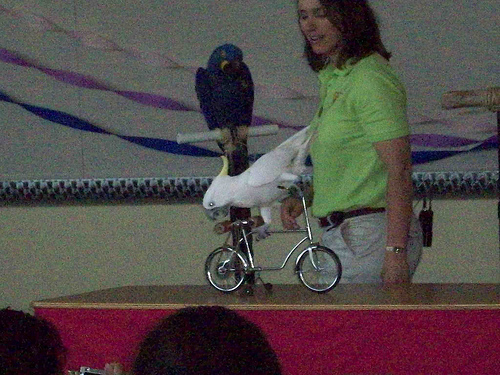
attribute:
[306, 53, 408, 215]
shirt — green, polo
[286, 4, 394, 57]
person's head — top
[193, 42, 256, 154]
bird —  blue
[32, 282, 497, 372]
stand — red, brown, wooden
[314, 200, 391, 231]
belt — woman's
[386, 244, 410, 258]
watch — small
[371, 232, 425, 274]
wrist — woman's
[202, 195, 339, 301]
toy bicycle — small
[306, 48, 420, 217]
polo — green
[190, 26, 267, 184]
parrot — blue, looking